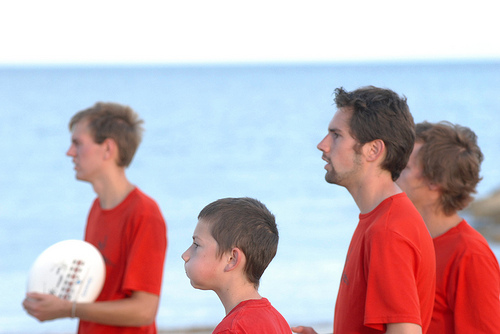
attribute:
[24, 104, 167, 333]
male — in background, at beach, looking left, in picture, in group, standing, on far right, to far right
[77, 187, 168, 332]
shirt — short sleeve, red, short sleeved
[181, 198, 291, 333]
male — holding breath, young, at beach, looking left, in picture, in group, standing, smaller, making face, small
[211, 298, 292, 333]
shirt — short sleeve, red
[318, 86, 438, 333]
male — at beach, looking left, in picture, looking forward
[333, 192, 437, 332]
shirt — short sleeve, red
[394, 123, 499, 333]
male — looking left, in picture, in group, standing, not showing face, at beach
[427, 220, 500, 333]
shirt — short sleeve, red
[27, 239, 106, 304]
frisbee — white, round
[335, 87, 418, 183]
hair — brown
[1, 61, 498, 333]
water — in background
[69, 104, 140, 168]
hair — sandy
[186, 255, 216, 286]
cheek — puffed out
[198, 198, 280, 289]
hair — brown